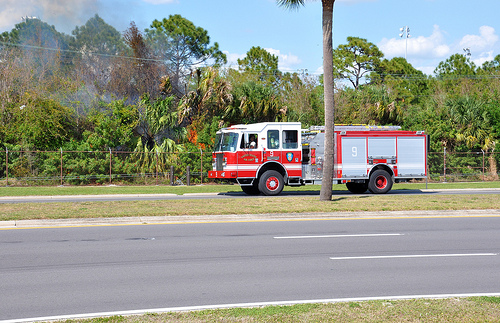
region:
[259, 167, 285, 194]
Front wheel of hauling truck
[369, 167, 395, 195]
Rear wheel of hauling truck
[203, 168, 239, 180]
Front bumper of hauling truck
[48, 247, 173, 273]
PART OF PAVED ROADWAY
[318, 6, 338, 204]
Tall tree near road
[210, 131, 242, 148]
Front windshield of truck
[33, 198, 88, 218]
Part of green grassy area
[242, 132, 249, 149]
Truck driver's side view mirror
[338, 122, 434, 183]
Part of hauling bed of truck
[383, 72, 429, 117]
Part of Summer tree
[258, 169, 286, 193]
front driver's side tire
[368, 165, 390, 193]
rear driver's side tire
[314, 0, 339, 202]
palm tree in foreground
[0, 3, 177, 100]
smoke in upper left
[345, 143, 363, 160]
number "9" on fire truck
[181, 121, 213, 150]
bit of visible fire directly in front of truck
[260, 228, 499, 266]
two white lines painted on roadway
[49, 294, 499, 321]
grass in foreground, bottom of picture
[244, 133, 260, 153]
man driving fire truck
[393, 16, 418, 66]
tall light structure at top right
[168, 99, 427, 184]
Fire engine on the road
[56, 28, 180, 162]
Smoke in the field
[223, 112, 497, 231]
red and white fire truck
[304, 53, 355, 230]
tree next to fire truck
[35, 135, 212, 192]
fence next to fire truck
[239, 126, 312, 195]
fire truck number 9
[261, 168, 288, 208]
red rims on tires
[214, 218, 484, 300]
White traffic lines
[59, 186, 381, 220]
Grass dividing the street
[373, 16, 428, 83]
Lights in the sky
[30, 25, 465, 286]
A fire truck is going down the street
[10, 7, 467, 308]
A fire truck is responding to a fire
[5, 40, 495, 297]
The truck is carrying firemen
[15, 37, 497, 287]
The truck has many big hoses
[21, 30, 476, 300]
The truck is operated by the city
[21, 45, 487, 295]
The vehicle is for emergencies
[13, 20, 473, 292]
The truck is moving quickly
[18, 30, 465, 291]
The truck is carrying ladders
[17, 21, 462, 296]
The truck is out in the sunshine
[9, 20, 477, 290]
The truck is headed toward the smoke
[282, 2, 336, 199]
palm tree by the road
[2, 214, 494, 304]
three lane road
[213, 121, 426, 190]
red fire truck on the sidewalk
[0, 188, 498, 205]
bicycle path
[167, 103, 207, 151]
fire in the woods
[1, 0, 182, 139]
smoke from the fire in the woods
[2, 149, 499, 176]
chain link fence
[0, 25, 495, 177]
woods beyond the fence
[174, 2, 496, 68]
partly cloudy sky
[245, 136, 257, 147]
fire engine driver